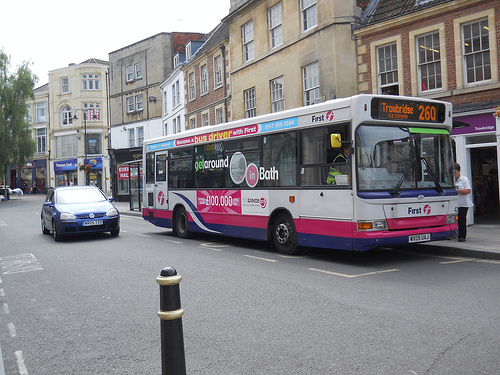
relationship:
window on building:
[336, 25, 436, 126] [39, 36, 482, 178]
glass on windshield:
[366, 134, 411, 182] [353, 118, 459, 193]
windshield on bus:
[353, 118, 459, 193] [126, 117, 420, 266]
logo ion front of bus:
[400, 198, 440, 220] [141, 92, 459, 254]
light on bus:
[354, 219, 375, 232] [141, 92, 459, 254]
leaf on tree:
[5, 151, 7, 158] [1, 48, 42, 200]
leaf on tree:
[12, 152, 19, 160] [1, 48, 42, 200]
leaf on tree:
[22, 145, 27, 152] [1, 48, 42, 200]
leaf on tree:
[17, 132, 24, 137] [1, 48, 42, 200]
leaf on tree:
[7, 92, 14, 109] [1, 48, 42, 200]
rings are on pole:
[154, 271, 187, 287] [158, 269, 188, 371]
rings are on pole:
[155, 305, 188, 319] [158, 269, 188, 371]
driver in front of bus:
[327, 146, 352, 187] [105, 83, 462, 279]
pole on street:
[153, 265, 194, 375] [48, 278, 301, 369]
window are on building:
[261, 7, 285, 44] [217, 1, 360, 91]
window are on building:
[235, 19, 255, 56] [217, 1, 360, 91]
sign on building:
[52, 156, 101, 171] [46, 53, 114, 200]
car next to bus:
[35, 179, 120, 242] [141, 92, 459, 254]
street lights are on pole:
[70, 109, 100, 124] [78, 121, 93, 186]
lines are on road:
[0, 311, 47, 373] [1, 268, 40, 371]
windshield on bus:
[353, 121, 455, 189] [116, 118, 472, 246]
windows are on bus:
[166, 120, 374, 188] [141, 92, 459, 254]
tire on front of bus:
[268, 206, 298, 255] [141, 92, 459, 254]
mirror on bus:
[329, 133, 344, 148] [141, 92, 459, 254]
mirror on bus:
[330, 133, 342, 148] [132, 85, 474, 267]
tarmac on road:
[173, 236, 414, 355] [1, 268, 500, 375]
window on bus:
[299, 120, 350, 190] [141, 92, 459, 254]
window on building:
[125, 65, 135, 82] [105, 30, 204, 197]